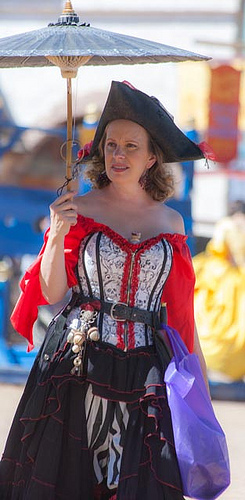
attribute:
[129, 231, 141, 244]
bottle — sticking 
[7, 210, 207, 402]
shirt — top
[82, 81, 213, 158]
pirate hat — black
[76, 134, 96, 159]
flowers — red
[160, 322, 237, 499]
bag — purple 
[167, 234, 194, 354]
red sleeve — frilly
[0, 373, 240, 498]
ground — grey, clean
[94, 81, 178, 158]
hat — boaters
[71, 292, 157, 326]
belt — black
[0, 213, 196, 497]
uniform — scary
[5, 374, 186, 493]
lace — red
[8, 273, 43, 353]
fabric — hanging down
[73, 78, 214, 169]
hat — black , triangular 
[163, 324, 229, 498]
bag — purple, paper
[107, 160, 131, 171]
lips — parted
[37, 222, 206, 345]
dress — black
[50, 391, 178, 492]
pattern skirt — random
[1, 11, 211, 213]
umbrella — old time, wood, open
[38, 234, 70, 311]
forearm — sunny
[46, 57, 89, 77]
umbrella opener — wooden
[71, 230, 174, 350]
bodice — black, white